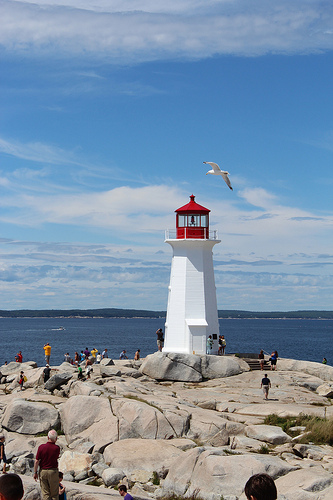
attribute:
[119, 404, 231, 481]
rocks — big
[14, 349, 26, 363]
fat person —  Small ,  fat, in red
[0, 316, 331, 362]
sea — calm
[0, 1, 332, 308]
sky — beautiful, blue, cloudy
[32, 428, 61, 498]
man — older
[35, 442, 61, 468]
shirt — red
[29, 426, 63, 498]
man — mature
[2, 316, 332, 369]
water — beautiful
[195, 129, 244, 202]
seagull —  in flight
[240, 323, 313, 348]
water — blue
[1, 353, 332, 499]
boulders — uneven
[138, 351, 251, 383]
rock — Large, heavy , grey 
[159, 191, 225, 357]
lighthouse — Large, tall, red, white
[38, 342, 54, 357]
shirt — yellow 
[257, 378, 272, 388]
shirt — black